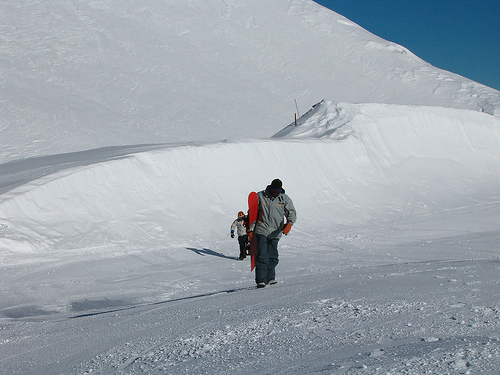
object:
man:
[248, 178, 297, 288]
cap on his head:
[269, 178, 284, 194]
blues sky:
[320, 1, 498, 91]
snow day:
[0, 0, 498, 374]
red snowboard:
[244, 190, 258, 272]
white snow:
[1, 1, 231, 375]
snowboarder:
[244, 177, 297, 289]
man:
[229, 209, 251, 262]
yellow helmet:
[237, 211, 245, 218]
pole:
[292, 111, 299, 127]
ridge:
[1, 99, 499, 197]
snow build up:
[301, 97, 497, 260]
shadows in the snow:
[0, 142, 185, 195]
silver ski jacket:
[256, 190, 296, 239]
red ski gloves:
[281, 222, 293, 235]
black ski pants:
[237, 234, 249, 257]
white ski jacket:
[230, 216, 250, 238]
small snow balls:
[193, 312, 206, 320]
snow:
[1, 2, 498, 178]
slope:
[0, 100, 277, 202]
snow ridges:
[273, 88, 499, 148]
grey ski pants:
[252, 232, 278, 283]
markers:
[289, 96, 301, 125]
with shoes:
[255, 282, 267, 289]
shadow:
[185, 245, 239, 263]